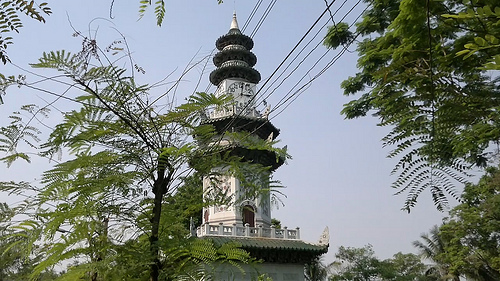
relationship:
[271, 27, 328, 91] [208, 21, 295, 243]
lines behind temple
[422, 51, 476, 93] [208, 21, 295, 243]
trees behind temple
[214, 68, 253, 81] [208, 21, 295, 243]
rings around temple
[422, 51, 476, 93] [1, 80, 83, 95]
trees on left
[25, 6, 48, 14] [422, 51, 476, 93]
leaves on trees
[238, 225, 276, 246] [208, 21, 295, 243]
railing on temple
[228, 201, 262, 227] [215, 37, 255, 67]
door on tower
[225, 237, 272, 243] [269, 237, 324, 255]
shingles on roof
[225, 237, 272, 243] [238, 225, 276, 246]
shingles on railing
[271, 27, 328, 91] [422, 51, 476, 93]
lines behind trees